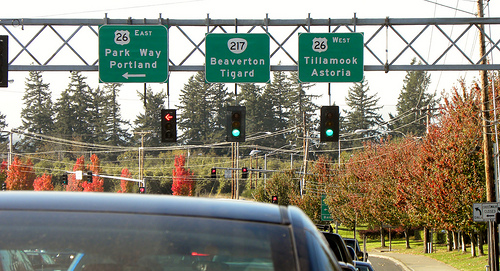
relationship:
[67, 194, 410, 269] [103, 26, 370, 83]
street has signs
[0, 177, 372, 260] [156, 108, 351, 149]
traffic has signals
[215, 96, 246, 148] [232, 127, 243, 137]
signal means go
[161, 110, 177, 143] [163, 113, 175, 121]
light means arrow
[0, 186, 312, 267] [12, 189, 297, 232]
car has hood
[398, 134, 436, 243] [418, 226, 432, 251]
tree has trunk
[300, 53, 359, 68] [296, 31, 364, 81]
tillamook on sign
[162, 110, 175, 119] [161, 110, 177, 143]
arrow on light